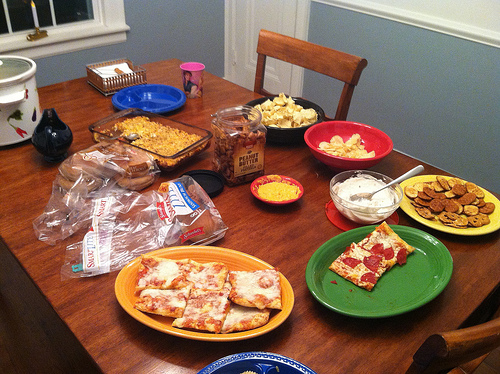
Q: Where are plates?
A: On the table.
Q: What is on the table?
A: Food.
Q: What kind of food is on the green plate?
A: Pizza.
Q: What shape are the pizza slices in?
A: Squares.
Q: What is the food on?
A: Table top.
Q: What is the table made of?
A: Wood.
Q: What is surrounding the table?
A: Chairs.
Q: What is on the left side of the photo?
A: Window.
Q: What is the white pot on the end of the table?
A: Crock pot.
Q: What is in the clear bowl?
A: Dip.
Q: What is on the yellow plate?
A: Crackers.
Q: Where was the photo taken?
A: In a dining room.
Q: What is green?
A: A plate.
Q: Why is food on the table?
A: To be eaten.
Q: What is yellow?
A: Two plates.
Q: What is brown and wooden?
A: Table.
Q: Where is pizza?
A: On plates.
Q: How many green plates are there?
A: One.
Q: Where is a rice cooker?
A: On the table.